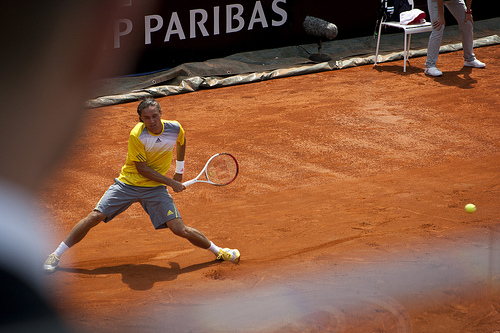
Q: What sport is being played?
A: Tennis.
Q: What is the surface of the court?
A: Red clay.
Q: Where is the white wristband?
A: On the tennis player's left wrist.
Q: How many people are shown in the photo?
A: Three.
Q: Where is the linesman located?
A: Standing in front of his chair.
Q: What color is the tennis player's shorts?
A: Grey.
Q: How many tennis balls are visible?
A: One.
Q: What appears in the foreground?
A: The side of a person's head.